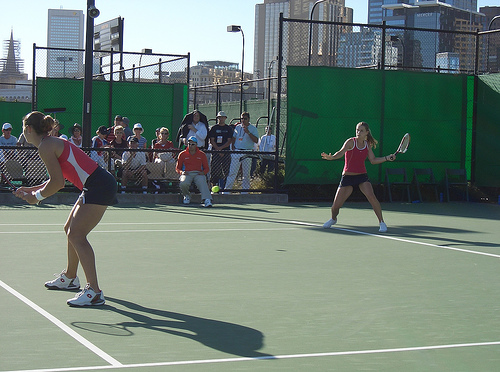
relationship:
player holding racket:
[319, 119, 400, 234] [391, 121, 414, 160]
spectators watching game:
[3, 106, 280, 181] [10, 75, 431, 320]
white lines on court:
[2, 219, 499, 370] [1, 195, 498, 370]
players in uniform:
[0, 94, 452, 292] [335, 137, 374, 187]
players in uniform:
[0, 94, 452, 292] [50, 134, 118, 214]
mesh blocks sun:
[300, 73, 464, 187] [302, 261, 465, 332]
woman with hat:
[124, 120, 147, 152] [131, 121, 144, 131]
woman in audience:
[124, 120, 147, 152] [0, 108, 282, 195]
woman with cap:
[0, 120, 20, 166] [2, 120, 14, 135]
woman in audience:
[0, 120, 20, 166] [2, 105, 282, 211]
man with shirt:
[179, 107, 210, 147] [180, 108, 193, 134]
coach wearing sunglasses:
[173, 135, 217, 206] [187, 140, 194, 146]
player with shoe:
[319, 119, 400, 234] [378, 218, 390, 235]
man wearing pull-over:
[174, 136, 219, 208] [174, 148, 211, 178]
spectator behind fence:
[156, 128, 174, 185] [3, 141, 277, 193]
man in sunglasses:
[175, 136, 214, 208] [187, 140, 194, 146]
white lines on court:
[292, 220, 499, 256] [0, 201, 499, 372]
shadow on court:
[105, 292, 280, 365] [124, 201, 377, 317]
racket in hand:
[388, 130, 418, 164] [382, 151, 398, 164]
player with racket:
[319, 119, 400, 234] [389, 132, 410, 156]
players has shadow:
[11, 108, 121, 308] [67, 292, 276, 359]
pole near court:
[223, 22, 253, 118] [0, 201, 499, 372]